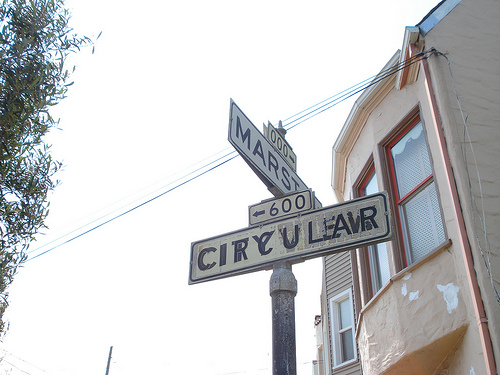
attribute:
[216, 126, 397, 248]
signs — several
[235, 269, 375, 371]
post — gray, metal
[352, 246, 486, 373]
wall — painted, chipped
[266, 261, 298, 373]
post pole — old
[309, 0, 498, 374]
building — yellow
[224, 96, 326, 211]
sign — old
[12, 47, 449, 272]
telephone wires — against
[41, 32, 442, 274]
wires — black, extending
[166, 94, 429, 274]
signs — white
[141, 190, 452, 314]
sign — white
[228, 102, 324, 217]
sign — Street sign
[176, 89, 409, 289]
sign — white, black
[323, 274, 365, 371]
window — rectangular, white trimmed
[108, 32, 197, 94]
sky — white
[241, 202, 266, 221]
arrow — black, pointing left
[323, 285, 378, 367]
window — white framed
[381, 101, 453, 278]
window — red trimmed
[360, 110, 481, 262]
windows — red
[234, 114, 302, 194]
name — Marst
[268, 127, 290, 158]
number — 000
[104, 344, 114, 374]
pole — power line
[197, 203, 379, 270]
name — painted over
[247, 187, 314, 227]
sign — white, small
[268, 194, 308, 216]
number — 600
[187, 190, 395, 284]
sign — white, black, old, Street sign, circular